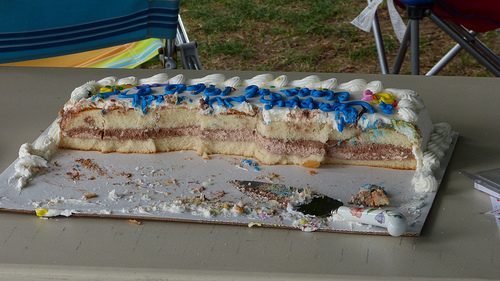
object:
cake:
[7, 74, 454, 193]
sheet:
[0, 114, 460, 237]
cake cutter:
[224, 178, 410, 239]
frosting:
[226, 179, 324, 208]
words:
[93, 82, 394, 115]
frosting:
[62, 72, 424, 122]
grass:
[131, 2, 499, 77]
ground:
[132, 0, 499, 79]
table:
[0, 64, 500, 280]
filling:
[65, 123, 417, 161]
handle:
[337, 204, 407, 237]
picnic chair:
[1, 0, 205, 70]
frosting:
[13, 111, 62, 188]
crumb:
[345, 182, 390, 207]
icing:
[360, 88, 379, 102]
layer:
[56, 136, 419, 171]